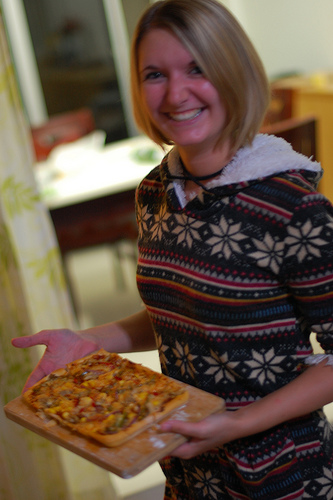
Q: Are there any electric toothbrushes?
A: No, there are no electric toothbrushes.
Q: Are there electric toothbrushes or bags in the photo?
A: No, there are no electric toothbrushes or bags.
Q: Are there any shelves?
A: No, there are no shelves.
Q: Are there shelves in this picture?
A: No, there are no shelves.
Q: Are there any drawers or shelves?
A: No, there are no shelves or drawers.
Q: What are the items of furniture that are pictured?
A: The pieces of furniture are chairs.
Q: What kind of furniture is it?
A: The pieces of furniture are chairs.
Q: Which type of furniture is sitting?
A: The furniture is chairs.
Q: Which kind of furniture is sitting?
A: The furniture is chairs.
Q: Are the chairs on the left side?
A: Yes, the chairs are on the left of the image.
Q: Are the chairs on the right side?
A: No, the chairs are on the left of the image.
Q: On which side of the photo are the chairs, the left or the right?
A: The chairs are on the left of the image.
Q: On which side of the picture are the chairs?
A: The chairs are on the left of the image.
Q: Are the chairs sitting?
A: Yes, the chairs are sitting.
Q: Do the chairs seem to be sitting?
A: Yes, the chairs are sitting.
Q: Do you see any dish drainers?
A: No, there are no dish drainers.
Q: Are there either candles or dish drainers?
A: No, there are no dish drainers or candles.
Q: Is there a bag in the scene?
A: No, there are no bags.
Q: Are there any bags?
A: No, there are no bags.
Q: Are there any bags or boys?
A: No, there are no bags or boys.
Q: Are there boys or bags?
A: No, there are no bags or boys.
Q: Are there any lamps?
A: No, there are no lamps.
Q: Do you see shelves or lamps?
A: No, there are no lamps or shelves.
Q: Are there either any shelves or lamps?
A: No, there are no lamps or shelves.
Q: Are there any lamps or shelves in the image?
A: No, there are no lamps or shelves.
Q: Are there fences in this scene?
A: No, there are no fences.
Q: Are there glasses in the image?
A: No, there are no glasses.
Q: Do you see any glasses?
A: No, there are no glasses.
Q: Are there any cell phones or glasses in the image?
A: No, there are no glasses or cell phones.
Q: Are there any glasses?
A: No, there are no glasses.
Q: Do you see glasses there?
A: No, there are no glasses.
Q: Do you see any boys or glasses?
A: No, there are no glasses or boys.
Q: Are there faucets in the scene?
A: No, there are no faucets.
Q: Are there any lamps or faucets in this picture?
A: No, there are no faucets or lamps.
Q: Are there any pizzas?
A: Yes, there is a pizza.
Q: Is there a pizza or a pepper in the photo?
A: Yes, there is a pizza.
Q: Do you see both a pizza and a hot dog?
A: No, there is a pizza but no hot dogs.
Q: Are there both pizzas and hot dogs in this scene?
A: No, there is a pizza but no hot dogs.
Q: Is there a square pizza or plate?
A: Yes, there is a square pizza.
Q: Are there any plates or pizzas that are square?
A: Yes, the pizza is square.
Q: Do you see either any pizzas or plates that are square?
A: Yes, the pizza is square.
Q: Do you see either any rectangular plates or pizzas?
A: Yes, there is a rectangular pizza.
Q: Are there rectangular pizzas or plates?
A: Yes, there is a rectangular pizza.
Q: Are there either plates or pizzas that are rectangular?
A: Yes, the pizza is rectangular.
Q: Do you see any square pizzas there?
A: Yes, there is a square pizza.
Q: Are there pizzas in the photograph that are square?
A: Yes, there is a pizza that is square.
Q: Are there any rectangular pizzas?
A: Yes, there is a rectangular pizza.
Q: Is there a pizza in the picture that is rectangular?
A: Yes, there is a pizza that is rectangular.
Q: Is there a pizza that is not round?
A: Yes, there is a rectangular pizza.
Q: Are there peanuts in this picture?
A: No, there are no peanuts.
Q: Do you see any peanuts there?
A: No, there are no peanuts.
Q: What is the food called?
A: The food is a pizza.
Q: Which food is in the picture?
A: The food is a pizza.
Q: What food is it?
A: The food is a pizza.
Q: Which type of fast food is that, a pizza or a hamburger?
A: This is a pizza.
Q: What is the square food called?
A: The food is a pizza.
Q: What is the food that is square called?
A: The food is a pizza.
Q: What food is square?
A: The food is a pizza.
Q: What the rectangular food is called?
A: The food is a pizza.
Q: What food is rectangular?
A: The food is a pizza.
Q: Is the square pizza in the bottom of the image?
A: Yes, the pizza is in the bottom of the image.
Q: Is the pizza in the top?
A: No, the pizza is in the bottom of the image.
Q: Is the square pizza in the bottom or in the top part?
A: The pizza is in the bottom of the image.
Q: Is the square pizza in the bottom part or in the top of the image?
A: The pizza is in the bottom of the image.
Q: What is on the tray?
A: The pizza is on the tray.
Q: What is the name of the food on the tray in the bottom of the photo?
A: The food is a pizza.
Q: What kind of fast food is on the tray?
A: The food is a pizza.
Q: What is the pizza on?
A: The pizza is on the tray.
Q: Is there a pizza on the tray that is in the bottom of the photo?
A: Yes, there is a pizza on the tray.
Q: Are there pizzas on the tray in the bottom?
A: Yes, there is a pizza on the tray.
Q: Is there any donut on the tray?
A: No, there is a pizza on the tray.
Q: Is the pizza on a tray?
A: Yes, the pizza is on a tray.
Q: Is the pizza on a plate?
A: No, the pizza is on a tray.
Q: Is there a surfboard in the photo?
A: No, there are no surfboards.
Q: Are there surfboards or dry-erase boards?
A: No, there are no surfboards or dry-erase boards.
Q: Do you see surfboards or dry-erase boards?
A: No, there are no surfboards or dry-erase boards.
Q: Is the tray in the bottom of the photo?
A: Yes, the tray is in the bottom of the image.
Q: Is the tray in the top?
A: No, the tray is in the bottom of the image.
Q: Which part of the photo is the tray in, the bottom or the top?
A: The tray is in the bottom of the image.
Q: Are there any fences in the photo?
A: No, there are no fences.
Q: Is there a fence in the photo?
A: No, there are no fences.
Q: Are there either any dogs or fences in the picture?
A: No, there are no fences or dogs.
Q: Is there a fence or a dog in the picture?
A: No, there are no fences or dogs.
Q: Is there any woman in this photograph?
A: Yes, there is a woman.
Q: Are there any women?
A: Yes, there is a woman.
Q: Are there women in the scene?
A: Yes, there is a woman.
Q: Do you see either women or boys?
A: Yes, there is a woman.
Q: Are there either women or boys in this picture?
A: Yes, there is a woman.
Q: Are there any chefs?
A: No, there are no chefs.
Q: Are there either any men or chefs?
A: No, there are no chefs or men.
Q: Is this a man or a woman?
A: This is a woman.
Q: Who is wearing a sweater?
A: The woman is wearing a sweater.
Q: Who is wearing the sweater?
A: The woman is wearing a sweater.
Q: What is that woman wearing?
A: The woman is wearing a sweater.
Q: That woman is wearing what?
A: The woman is wearing a sweater.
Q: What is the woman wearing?
A: The woman is wearing a sweater.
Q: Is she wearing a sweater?
A: Yes, the woman is wearing a sweater.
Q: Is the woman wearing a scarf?
A: No, the woman is wearing a sweater.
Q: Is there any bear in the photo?
A: No, there are no bears.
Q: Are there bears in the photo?
A: No, there are no bears.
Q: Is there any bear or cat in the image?
A: No, there are no bears or cats.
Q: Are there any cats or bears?
A: No, there are no bears or cats.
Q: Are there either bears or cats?
A: No, there are no bears or cats.